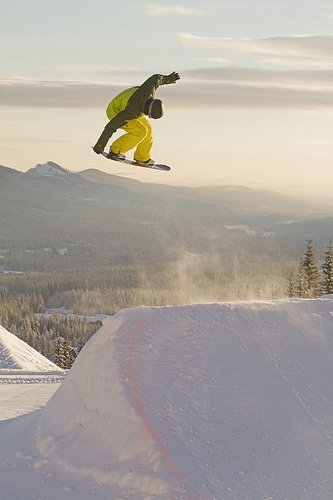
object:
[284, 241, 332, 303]
pine trees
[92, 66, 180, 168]
snowboarder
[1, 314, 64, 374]
slope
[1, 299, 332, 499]
snow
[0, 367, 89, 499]
ground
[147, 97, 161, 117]
hat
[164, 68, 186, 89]
gloves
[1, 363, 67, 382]
line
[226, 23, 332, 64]
clouds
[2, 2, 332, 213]
sky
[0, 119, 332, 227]
fog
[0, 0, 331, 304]
background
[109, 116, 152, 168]
pants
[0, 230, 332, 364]
trees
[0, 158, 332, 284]
hill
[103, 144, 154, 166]
feet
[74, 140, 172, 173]
board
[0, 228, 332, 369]
forest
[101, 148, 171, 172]
snowboard